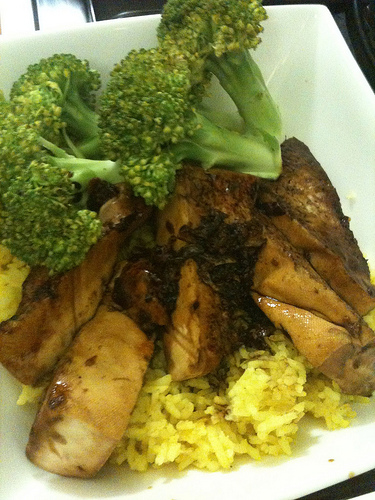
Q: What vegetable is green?
A: Broccolli.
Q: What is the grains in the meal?
A: Yellow rice.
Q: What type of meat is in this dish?
A: Chicken.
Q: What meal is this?
A: Dinner.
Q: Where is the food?
A: On a white plane.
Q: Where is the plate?
A: On the table.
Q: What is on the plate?
A: A dinner meal.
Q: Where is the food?
A: On the plate.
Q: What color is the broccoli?
A: Green.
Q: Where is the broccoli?
A: At the top of the plate.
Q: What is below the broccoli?
A: Chicken.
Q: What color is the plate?
A: White.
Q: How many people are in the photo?
A: None.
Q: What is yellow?
A: Some of the food.